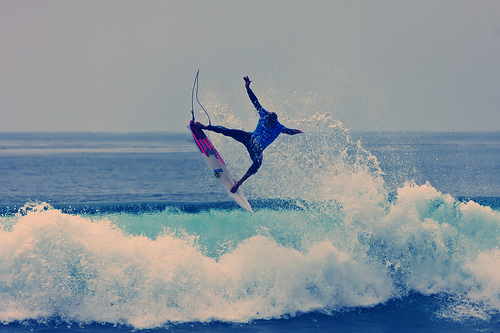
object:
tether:
[190, 69, 212, 125]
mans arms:
[240, 77, 271, 119]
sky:
[3, 4, 494, 134]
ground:
[429, 99, 465, 152]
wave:
[3, 206, 498, 321]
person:
[196, 72, 308, 194]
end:
[187, 71, 212, 136]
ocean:
[1, 131, 498, 331]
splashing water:
[0, 75, 493, 330]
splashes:
[305, 144, 387, 199]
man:
[195, 73, 305, 198]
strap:
[203, 120, 213, 131]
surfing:
[185, 69, 256, 214]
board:
[187, 118, 254, 211]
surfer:
[191, 75, 311, 195]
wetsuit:
[193, 85, 293, 195]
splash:
[136, 236, 211, 294]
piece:
[182, 97, 199, 127]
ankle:
[199, 121, 209, 135]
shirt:
[250, 105, 294, 155]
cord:
[187, 67, 216, 127]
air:
[111, 73, 216, 291]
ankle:
[229, 185, 237, 201]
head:
[260, 111, 286, 127]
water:
[7, 127, 484, 292]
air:
[32, 54, 144, 144]